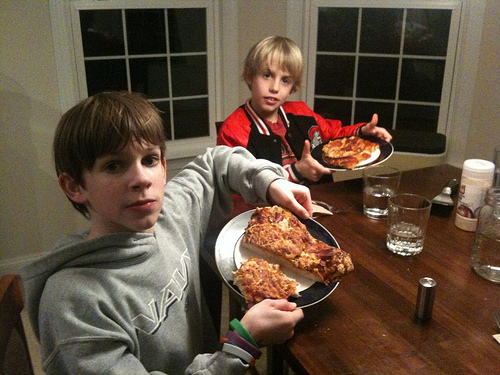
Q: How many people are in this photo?
A: Two.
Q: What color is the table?
A: Brown.